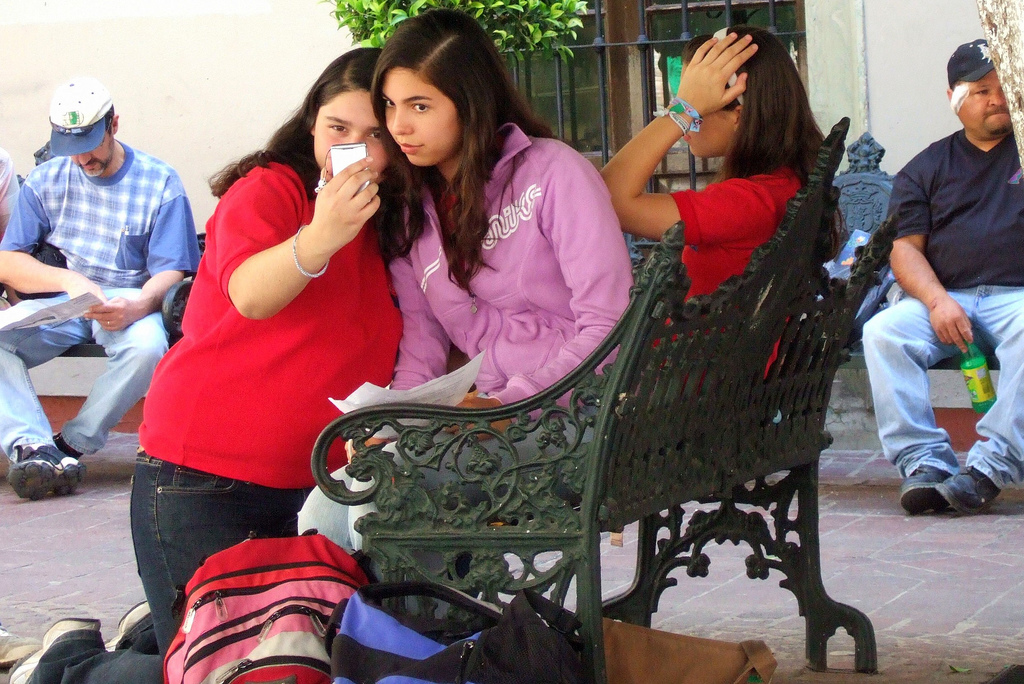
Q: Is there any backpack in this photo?
A: Yes, there is a backpack.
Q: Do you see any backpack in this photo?
A: Yes, there is a backpack.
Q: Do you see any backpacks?
A: Yes, there is a backpack.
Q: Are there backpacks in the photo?
A: Yes, there is a backpack.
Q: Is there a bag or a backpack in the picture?
A: Yes, there is a backpack.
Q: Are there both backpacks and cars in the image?
A: No, there is a backpack but no cars.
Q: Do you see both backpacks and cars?
A: No, there is a backpack but no cars.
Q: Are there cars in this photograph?
A: No, there are no cars.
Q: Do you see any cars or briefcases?
A: No, there are no cars or briefcases.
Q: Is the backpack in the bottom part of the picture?
A: Yes, the backpack is in the bottom of the image.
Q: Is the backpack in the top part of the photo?
A: No, the backpack is in the bottom of the image.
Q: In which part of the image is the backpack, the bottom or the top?
A: The backpack is in the bottom of the image.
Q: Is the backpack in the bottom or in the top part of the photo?
A: The backpack is in the bottom of the image.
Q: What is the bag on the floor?
A: The bag is a backpack.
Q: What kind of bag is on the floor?
A: The bag is a backpack.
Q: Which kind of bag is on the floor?
A: The bag is a backpack.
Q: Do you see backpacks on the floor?
A: Yes, there is a backpack on the floor.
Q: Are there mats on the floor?
A: No, there is a backpack on the floor.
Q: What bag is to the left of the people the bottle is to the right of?
A: The bag is a backpack.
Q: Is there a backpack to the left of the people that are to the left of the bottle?
A: Yes, there is a backpack to the left of the people.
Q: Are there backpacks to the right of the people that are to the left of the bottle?
A: No, the backpack is to the left of the people.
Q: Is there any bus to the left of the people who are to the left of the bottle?
A: No, there is a backpack to the left of the people.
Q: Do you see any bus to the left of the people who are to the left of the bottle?
A: No, there is a backpack to the left of the people.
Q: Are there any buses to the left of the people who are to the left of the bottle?
A: No, there is a backpack to the left of the people.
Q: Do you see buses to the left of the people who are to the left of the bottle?
A: No, there is a backpack to the left of the people.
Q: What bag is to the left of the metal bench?
A: The bag is a backpack.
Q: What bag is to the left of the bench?
A: The bag is a backpack.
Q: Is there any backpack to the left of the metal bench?
A: Yes, there is a backpack to the left of the bench.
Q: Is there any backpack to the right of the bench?
A: No, the backpack is to the left of the bench.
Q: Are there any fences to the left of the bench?
A: No, there is a backpack to the left of the bench.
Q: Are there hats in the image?
A: Yes, there is a hat.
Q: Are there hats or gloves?
A: Yes, there is a hat.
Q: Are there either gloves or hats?
A: Yes, there is a hat.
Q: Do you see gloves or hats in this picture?
A: Yes, there is a hat.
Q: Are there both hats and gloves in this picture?
A: No, there is a hat but no gloves.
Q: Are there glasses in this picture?
A: No, there are no glasses.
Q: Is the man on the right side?
A: Yes, the man is on the right of the image.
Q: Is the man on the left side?
A: No, the man is on the right of the image.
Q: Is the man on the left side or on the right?
A: The man is on the right of the image.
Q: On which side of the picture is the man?
A: The man is on the right of the image.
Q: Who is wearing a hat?
A: The man is wearing a hat.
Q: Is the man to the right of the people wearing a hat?
A: Yes, the man is wearing a hat.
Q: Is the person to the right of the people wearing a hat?
A: Yes, the man is wearing a hat.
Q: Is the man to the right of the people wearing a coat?
A: No, the man is wearing a hat.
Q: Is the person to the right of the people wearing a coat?
A: No, the man is wearing a hat.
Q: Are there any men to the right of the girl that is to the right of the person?
A: Yes, there is a man to the right of the girl.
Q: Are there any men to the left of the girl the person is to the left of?
A: No, the man is to the right of the girl.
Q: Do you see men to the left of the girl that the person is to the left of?
A: No, the man is to the right of the girl.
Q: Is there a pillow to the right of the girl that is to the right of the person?
A: No, there is a man to the right of the girl.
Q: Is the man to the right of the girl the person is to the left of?
A: Yes, the man is to the right of the girl.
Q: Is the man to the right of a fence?
A: No, the man is to the right of the girl.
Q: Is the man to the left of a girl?
A: No, the man is to the right of a girl.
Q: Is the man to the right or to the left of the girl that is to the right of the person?
A: The man is to the right of the girl.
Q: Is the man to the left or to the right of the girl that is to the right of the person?
A: The man is to the right of the girl.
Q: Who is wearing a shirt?
A: The man is wearing a shirt.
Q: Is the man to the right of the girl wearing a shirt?
A: Yes, the man is wearing a shirt.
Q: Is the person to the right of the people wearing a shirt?
A: Yes, the man is wearing a shirt.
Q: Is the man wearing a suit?
A: No, the man is wearing a shirt.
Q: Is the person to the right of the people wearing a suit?
A: No, the man is wearing a shirt.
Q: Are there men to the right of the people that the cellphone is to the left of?
A: Yes, there is a man to the right of the people.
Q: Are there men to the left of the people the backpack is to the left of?
A: No, the man is to the right of the people.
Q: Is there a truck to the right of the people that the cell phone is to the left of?
A: No, there is a man to the right of the people.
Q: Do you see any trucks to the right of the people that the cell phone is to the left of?
A: No, there is a man to the right of the people.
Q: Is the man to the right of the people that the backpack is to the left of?
A: Yes, the man is to the right of the people.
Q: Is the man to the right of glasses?
A: No, the man is to the right of the people.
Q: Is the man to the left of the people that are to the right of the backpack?
A: No, the man is to the right of the people.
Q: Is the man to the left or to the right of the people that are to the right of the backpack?
A: The man is to the right of the people.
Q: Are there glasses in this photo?
A: No, there are no glasses.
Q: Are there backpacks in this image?
A: Yes, there is a backpack.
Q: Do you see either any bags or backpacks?
A: Yes, there is a backpack.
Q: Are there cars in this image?
A: No, there are no cars.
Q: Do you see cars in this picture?
A: No, there are no cars.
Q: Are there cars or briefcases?
A: No, there are no cars or briefcases.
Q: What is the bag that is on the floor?
A: The bag is a backpack.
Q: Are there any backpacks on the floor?
A: Yes, there is a backpack on the floor.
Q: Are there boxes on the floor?
A: No, there is a backpack on the floor.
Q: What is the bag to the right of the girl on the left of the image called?
A: The bag is a backpack.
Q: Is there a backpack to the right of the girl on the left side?
A: Yes, there is a backpack to the right of the girl.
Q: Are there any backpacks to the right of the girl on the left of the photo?
A: Yes, there is a backpack to the right of the girl.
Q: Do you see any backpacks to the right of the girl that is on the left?
A: Yes, there is a backpack to the right of the girl.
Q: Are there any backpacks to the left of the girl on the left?
A: No, the backpack is to the right of the girl.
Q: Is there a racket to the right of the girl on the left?
A: No, there is a backpack to the right of the girl.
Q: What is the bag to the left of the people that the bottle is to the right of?
A: The bag is a backpack.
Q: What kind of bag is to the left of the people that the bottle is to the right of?
A: The bag is a backpack.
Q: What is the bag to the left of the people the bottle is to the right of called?
A: The bag is a backpack.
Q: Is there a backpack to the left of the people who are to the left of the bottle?
A: Yes, there is a backpack to the left of the people.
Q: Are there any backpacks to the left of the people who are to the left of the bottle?
A: Yes, there is a backpack to the left of the people.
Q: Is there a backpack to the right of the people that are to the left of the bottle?
A: No, the backpack is to the left of the people.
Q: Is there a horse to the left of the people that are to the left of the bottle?
A: No, there is a backpack to the left of the people.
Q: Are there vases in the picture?
A: No, there are no vases.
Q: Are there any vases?
A: No, there are no vases.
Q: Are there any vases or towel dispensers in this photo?
A: No, there are no vases or towel dispensers.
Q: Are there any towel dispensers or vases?
A: No, there are no vases or towel dispensers.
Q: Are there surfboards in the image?
A: No, there are no surfboards.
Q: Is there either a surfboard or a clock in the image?
A: No, there are no surfboards or clocks.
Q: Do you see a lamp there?
A: No, there are no lamps.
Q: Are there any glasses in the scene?
A: No, there are no glasses.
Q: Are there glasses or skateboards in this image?
A: No, there are no glasses or skateboards.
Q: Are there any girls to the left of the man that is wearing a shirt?
A: Yes, there is a girl to the left of the man.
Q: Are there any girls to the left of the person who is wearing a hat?
A: Yes, there is a girl to the left of the man.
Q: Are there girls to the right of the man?
A: No, the girl is to the left of the man.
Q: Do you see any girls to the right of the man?
A: No, the girl is to the left of the man.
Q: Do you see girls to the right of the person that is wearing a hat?
A: No, the girl is to the left of the man.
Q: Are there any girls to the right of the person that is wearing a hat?
A: No, the girl is to the left of the man.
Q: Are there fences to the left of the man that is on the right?
A: No, there is a girl to the left of the man.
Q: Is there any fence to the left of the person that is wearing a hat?
A: No, there is a girl to the left of the man.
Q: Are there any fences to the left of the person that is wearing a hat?
A: No, there is a girl to the left of the man.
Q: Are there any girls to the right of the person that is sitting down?
A: Yes, there is a girl to the right of the person.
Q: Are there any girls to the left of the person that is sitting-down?
A: No, the girl is to the right of the person.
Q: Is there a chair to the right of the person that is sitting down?
A: No, there is a girl to the right of the person.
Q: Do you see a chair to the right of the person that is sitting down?
A: No, there is a girl to the right of the person.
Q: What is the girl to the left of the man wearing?
A: The girl is wearing a shirt.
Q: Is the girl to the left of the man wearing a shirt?
A: Yes, the girl is wearing a shirt.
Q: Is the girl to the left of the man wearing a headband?
A: No, the girl is wearing a shirt.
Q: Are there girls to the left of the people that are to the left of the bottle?
A: Yes, there is a girl to the left of the people.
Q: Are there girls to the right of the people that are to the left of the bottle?
A: No, the girl is to the left of the people.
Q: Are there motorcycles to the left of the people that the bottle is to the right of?
A: No, there is a girl to the left of the people.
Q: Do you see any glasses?
A: No, there are no glasses.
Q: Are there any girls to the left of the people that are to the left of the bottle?
A: Yes, there is a girl to the left of the people.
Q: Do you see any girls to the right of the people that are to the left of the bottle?
A: No, the girl is to the left of the people.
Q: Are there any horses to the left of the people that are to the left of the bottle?
A: No, there is a girl to the left of the people.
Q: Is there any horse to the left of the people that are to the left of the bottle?
A: No, there is a girl to the left of the people.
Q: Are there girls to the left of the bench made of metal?
A: Yes, there is a girl to the left of the bench.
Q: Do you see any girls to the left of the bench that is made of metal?
A: Yes, there is a girl to the left of the bench.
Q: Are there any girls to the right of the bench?
A: No, the girl is to the left of the bench.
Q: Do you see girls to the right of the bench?
A: No, the girl is to the left of the bench.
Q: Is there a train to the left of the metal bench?
A: No, there is a girl to the left of the bench.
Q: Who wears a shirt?
A: The girl wears a shirt.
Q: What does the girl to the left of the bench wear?
A: The girl wears a shirt.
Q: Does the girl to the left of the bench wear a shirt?
A: Yes, the girl wears a shirt.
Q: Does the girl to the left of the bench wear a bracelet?
A: No, the girl wears a shirt.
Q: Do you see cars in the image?
A: No, there are no cars.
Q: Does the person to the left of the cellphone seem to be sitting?
A: Yes, the person is sitting.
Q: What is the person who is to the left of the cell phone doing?
A: The person is sitting.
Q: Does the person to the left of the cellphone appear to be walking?
A: No, the person is sitting.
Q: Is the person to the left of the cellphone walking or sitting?
A: The person is sitting.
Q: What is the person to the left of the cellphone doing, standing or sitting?
A: The person is sitting.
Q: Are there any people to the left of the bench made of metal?
A: Yes, there is a person to the left of the bench.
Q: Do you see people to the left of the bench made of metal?
A: Yes, there is a person to the left of the bench.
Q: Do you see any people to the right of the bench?
A: No, the person is to the left of the bench.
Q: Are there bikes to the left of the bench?
A: No, there is a person to the left of the bench.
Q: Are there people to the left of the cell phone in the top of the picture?
A: Yes, there is a person to the left of the cellphone.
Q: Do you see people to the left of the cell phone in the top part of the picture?
A: Yes, there is a person to the left of the cellphone.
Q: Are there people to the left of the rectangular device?
A: Yes, there is a person to the left of the cellphone.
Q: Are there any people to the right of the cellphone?
A: No, the person is to the left of the cellphone.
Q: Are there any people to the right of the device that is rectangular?
A: No, the person is to the left of the cellphone.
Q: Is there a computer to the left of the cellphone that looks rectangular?
A: No, there is a person to the left of the cell phone.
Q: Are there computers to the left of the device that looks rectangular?
A: No, there is a person to the left of the cell phone.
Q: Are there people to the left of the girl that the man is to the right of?
A: Yes, there is a person to the left of the girl.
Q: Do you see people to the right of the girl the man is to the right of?
A: No, the person is to the left of the girl.